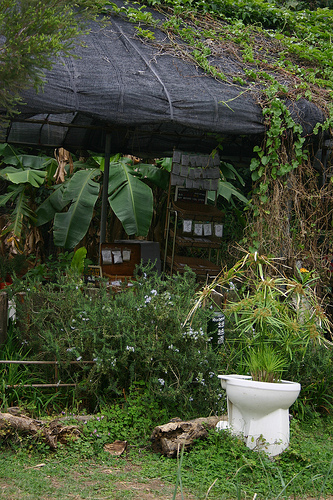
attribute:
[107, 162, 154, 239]
banana leaf — green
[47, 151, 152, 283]
leaves — flat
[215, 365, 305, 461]
toilet — old, white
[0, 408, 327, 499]
ground — green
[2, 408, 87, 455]
log — rotten, grey, part of tree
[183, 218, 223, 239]
papers — shaded, small, white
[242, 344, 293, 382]
grass — inside toilet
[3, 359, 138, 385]
fence — inside weeds, metalic, metal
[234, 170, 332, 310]
roots — overgrown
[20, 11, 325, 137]
roof — grey, black, above everything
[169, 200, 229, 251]
baskets — wicker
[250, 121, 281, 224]
vines — hanging, long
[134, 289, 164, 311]
flower — white, small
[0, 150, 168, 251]
tree leaves — large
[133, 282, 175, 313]
flowers — white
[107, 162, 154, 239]
leaf — giant, green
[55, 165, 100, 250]
leaf — giant, green